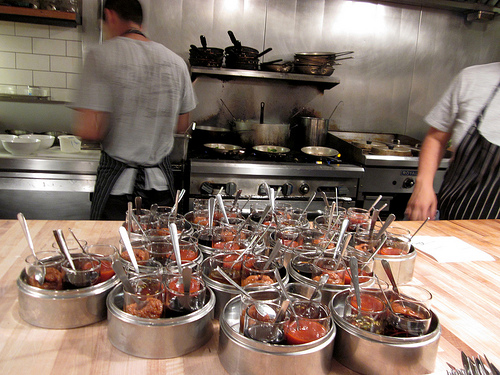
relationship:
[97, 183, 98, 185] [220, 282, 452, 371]
edge of sufuria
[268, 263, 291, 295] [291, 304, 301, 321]
handle of spoon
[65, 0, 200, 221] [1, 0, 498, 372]
guy in kitchen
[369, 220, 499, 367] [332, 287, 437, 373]
table next to pot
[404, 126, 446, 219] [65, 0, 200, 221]
arm of guy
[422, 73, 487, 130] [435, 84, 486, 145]
apron on front of man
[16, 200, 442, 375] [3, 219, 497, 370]
containers on table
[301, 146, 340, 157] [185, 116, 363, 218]
pan on stove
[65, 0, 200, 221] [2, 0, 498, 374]
guy with camera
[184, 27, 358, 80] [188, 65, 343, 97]
pots on shelf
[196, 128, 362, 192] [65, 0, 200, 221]
stove next to guy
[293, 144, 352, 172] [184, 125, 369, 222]
pan on stove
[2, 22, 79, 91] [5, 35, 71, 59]
wall made of bricks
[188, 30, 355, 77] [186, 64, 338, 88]
pots on shelf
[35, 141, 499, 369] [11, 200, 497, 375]
dishes on table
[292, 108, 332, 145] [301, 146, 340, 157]
pot by pan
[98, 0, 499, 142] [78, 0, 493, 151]
oven wall on oven wall